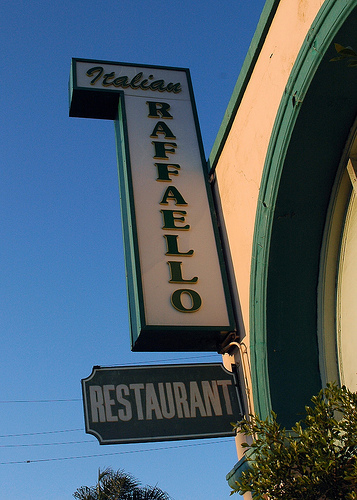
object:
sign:
[71, 51, 241, 351]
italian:
[83, 62, 185, 99]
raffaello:
[143, 93, 206, 314]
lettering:
[86, 375, 239, 426]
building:
[207, 0, 357, 500]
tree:
[228, 381, 357, 500]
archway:
[244, 0, 356, 438]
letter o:
[168, 284, 207, 314]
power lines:
[0, 428, 233, 466]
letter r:
[144, 93, 175, 124]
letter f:
[151, 135, 181, 161]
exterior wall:
[205, 0, 331, 442]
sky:
[2, 0, 267, 500]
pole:
[234, 329, 252, 424]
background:
[0, 0, 357, 500]